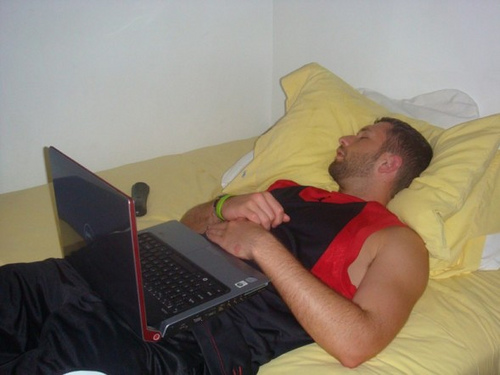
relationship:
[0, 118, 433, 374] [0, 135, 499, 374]
man on bed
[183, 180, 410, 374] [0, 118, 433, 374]
shirt on man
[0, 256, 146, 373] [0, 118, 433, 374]
pants on man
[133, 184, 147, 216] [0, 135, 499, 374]
control on bed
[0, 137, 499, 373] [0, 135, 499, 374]
sheet on bed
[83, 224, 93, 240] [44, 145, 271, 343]
logo on laptop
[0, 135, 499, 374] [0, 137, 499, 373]
bed has sheet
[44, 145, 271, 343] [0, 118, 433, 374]
laptop on man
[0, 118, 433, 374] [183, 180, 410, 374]
man wears shirt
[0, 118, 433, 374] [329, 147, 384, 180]
man has beard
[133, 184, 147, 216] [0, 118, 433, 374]
control near man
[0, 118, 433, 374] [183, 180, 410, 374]
man wearing shirt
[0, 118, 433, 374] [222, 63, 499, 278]
man laying on pillowcase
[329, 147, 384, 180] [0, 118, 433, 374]
beard on man